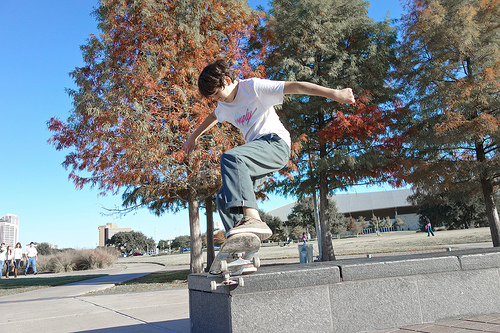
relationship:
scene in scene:
[0, 0, 499, 333] [3, 3, 498, 333]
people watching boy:
[0, 239, 38, 279] [186, 59, 356, 240]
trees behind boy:
[43, 2, 500, 262] [186, 59, 356, 240]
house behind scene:
[328, 189, 425, 237] [0, 0, 499, 333]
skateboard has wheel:
[207, 232, 261, 292] [254, 258, 261, 269]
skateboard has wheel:
[207, 232, 261, 292] [218, 261, 228, 275]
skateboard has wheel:
[207, 232, 261, 292] [209, 281, 217, 292]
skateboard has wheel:
[207, 232, 261, 292] [236, 276, 245, 290]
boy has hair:
[186, 59, 356, 240] [196, 63, 235, 96]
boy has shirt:
[186, 59, 356, 240] [209, 78, 291, 145]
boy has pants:
[186, 59, 356, 240] [217, 134, 293, 239]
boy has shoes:
[186, 59, 356, 240] [226, 221, 271, 239]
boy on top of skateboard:
[186, 59, 356, 240] [207, 232, 261, 292]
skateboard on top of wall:
[207, 232, 261, 292] [185, 246, 499, 333]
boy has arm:
[186, 59, 356, 240] [257, 78, 355, 105]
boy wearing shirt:
[186, 59, 356, 240] [209, 78, 291, 145]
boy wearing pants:
[186, 59, 356, 240] [217, 134, 293, 239]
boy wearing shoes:
[186, 59, 356, 240] [226, 221, 271, 239]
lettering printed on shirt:
[233, 109, 256, 125] [209, 78, 291, 145]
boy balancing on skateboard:
[186, 59, 356, 240] [207, 232, 261, 292]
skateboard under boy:
[207, 232, 261, 292] [186, 59, 356, 240]